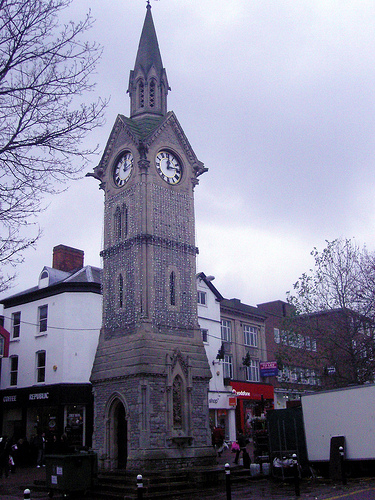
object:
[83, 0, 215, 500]
clocktower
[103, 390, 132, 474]
doorway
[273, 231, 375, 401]
tree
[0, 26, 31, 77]
branches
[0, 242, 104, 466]
building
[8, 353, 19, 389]
windows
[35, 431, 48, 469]
people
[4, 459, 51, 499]
sidewalk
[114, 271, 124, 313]
windows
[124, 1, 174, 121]
top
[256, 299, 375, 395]
buildings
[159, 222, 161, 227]
lights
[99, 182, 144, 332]
front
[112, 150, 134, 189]
clock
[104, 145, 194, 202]
top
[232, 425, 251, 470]
person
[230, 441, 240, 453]
bag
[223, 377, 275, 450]
front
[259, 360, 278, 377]
sign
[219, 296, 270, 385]
building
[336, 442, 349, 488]
posts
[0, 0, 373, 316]
sky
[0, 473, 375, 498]
ground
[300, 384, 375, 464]
structure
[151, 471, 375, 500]
street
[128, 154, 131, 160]
numbers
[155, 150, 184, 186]
clock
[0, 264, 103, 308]
roof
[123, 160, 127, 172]
hands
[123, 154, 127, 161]
number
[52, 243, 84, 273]
chimney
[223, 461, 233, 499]
pole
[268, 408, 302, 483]
trashbin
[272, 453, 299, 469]
roll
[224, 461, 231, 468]
tip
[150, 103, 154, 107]
window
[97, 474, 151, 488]
stairs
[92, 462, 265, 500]
bottom